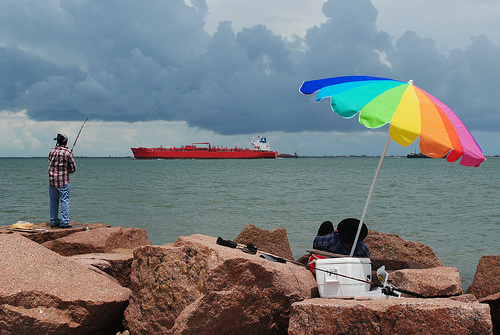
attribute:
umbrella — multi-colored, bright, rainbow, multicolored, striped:
[289, 70, 497, 261]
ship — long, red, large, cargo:
[128, 136, 280, 164]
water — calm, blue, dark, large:
[0, 158, 498, 258]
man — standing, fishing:
[44, 130, 83, 240]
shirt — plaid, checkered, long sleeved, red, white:
[45, 147, 79, 189]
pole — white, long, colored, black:
[68, 119, 88, 157]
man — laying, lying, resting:
[312, 217, 372, 253]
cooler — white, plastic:
[313, 255, 374, 302]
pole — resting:
[260, 252, 430, 299]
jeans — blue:
[46, 184, 72, 227]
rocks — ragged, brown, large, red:
[8, 223, 497, 334]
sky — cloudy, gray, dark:
[1, 1, 497, 160]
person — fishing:
[37, 124, 71, 230]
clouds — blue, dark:
[8, 10, 285, 134]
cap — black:
[339, 216, 367, 243]